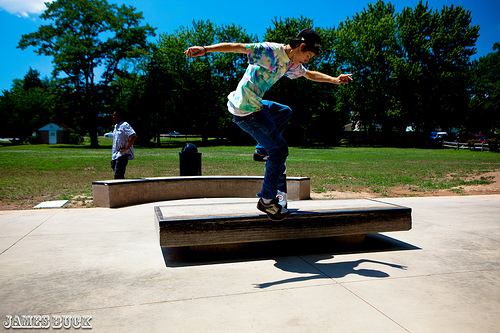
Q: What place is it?
A: It is a park.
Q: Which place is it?
A: It is a park.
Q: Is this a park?
A: Yes, it is a park.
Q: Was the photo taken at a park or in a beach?
A: It was taken at a park.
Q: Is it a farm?
A: No, it is a park.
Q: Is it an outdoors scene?
A: Yes, it is outdoors.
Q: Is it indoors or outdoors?
A: It is outdoors.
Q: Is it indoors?
A: No, it is outdoors.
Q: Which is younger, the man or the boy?
A: The boy is younger than the man.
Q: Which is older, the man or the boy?
A: The man is older than the boy.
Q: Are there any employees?
A: No, there are no employees.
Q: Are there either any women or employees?
A: No, there are no employees or women.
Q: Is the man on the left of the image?
A: Yes, the man is on the left of the image.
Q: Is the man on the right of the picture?
A: No, the man is on the left of the image.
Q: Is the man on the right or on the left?
A: The man is on the left of the image.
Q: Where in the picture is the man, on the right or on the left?
A: The man is on the left of the image.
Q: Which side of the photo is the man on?
A: The man is on the left of the image.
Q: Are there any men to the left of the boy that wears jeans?
A: Yes, there is a man to the left of the boy.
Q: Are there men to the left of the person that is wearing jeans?
A: Yes, there is a man to the left of the boy.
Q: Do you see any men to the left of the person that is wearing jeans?
A: Yes, there is a man to the left of the boy.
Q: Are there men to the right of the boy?
A: No, the man is to the left of the boy.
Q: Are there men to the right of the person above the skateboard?
A: No, the man is to the left of the boy.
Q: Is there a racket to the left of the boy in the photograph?
A: No, there is a man to the left of the boy.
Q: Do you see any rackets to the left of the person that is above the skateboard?
A: No, there is a man to the left of the boy.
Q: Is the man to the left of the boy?
A: Yes, the man is to the left of the boy.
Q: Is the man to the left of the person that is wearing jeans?
A: Yes, the man is to the left of the boy.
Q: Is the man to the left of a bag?
A: No, the man is to the left of the boy.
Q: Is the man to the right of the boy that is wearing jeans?
A: No, the man is to the left of the boy.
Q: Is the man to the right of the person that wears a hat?
A: No, the man is to the left of the boy.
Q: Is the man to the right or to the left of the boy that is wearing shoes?
A: The man is to the left of the boy.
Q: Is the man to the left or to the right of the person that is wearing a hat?
A: The man is to the left of the boy.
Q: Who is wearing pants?
A: The man is wearing pants.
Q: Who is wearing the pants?
A: The man is wearing pants.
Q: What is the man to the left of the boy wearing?
A: The man is wearing trousers.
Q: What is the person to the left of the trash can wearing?
A: The man is wearing trousers.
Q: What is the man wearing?
A: The man is wearing trousers.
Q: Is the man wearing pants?
A: Yes, the man is wearing pants.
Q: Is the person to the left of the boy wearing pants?
A: Yes, the man is wearing pants.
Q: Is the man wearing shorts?
A: No, the man is wearing pants.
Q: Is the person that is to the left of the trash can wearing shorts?
A: No, the man is wearing pants.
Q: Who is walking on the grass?
A: The man is walking on the grass.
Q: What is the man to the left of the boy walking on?
A: The man is walking on the grass.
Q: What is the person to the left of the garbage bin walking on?
A: The man is walking on the grass.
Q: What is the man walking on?
A: The man is walking on the grass.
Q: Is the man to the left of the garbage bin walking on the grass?
A: Yes, the man is walking on the grass.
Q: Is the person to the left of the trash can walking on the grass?
A: Yes, the man is walking on the grass.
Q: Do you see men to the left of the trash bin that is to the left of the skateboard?
A: Yes, there is a man to the left of the trash bin.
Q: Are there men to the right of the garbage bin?
A: No, the man is to the left of the garbage bin.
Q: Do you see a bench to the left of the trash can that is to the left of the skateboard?
A: No, there is a man to the left of the garbage can.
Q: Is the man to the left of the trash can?
A: Yes, the man is to the left of the trash can.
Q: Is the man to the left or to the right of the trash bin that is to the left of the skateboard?
A: The man is to the left of the trash bin.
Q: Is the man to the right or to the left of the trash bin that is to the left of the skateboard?
A: The man is to the left of the trash bin.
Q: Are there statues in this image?
A: No, there are no statues.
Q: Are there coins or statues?
A: No, there are no statues or coins.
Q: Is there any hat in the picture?
A: Yes, there is a hat.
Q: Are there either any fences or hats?
A: Yes, there is a hat.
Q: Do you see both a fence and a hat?
A: No, there is a hat but no fences.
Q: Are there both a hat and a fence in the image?
A: No, there is a hat but no fences.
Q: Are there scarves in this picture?
A: No, there are no scarves.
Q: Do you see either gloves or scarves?
A: No, there are no scarves or gloves.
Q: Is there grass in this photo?
A: Yes, there is grass.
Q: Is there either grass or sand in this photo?
A: Yes, there is grass.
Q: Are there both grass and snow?
A: No, there is grass but no snow.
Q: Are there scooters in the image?
A: No, there are no scooters.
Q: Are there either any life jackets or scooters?
A: No, there are no scooters or life jackets.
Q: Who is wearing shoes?
A: The boy is wearing shoes.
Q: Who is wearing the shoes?
A: The boy is wearing shoes.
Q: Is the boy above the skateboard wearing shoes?
A: Yes, the boy is wearing shoes.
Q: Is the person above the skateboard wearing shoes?
A: Yes, the boy is wearing shoes.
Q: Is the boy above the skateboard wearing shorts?
A: No, the boy is wearing shoes.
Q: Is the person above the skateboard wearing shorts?
A: No, the boy is wearing shoes.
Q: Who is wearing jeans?
A: The boy is wearing jeans.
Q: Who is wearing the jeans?
A: The boy is wearing jeans.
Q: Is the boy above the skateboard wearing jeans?
A: Yes, the boy is wearing jeans.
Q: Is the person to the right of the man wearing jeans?
A: Yes, the boy is wearing jeans.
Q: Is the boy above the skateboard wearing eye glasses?
A: No, the boy is wearing jeans.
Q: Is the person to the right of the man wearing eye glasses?
A: No, the boy is wearing jeans.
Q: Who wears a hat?
A: The boy wears a hat.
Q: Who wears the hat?
A: The boy wears a hat.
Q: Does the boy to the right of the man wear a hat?
A: Yes, the boy wears a hat.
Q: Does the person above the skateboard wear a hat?
A: Yes, the boy wears a hat.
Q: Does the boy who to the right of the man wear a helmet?
A: No, the boy wears a hat.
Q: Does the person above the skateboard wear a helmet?
A: No, the boy wears a hat.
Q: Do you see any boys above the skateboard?
A: Yes, there is a boy above the skateboard.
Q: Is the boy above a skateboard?
A: Yes, the boy is above a skateboard.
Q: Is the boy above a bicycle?
A: No, the boy is above a skateboard.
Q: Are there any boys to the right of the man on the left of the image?
A: Yes, there is a boy to the right of the man.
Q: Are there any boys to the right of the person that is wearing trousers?
A: Yes, there is a boy to the right of the man.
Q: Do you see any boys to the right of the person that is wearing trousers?
A: Yes, there is a boy to the right of the man.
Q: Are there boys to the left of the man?
A: No, the boy is to the right of the man.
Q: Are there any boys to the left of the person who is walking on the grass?
A: No, the boy is to the right of the man.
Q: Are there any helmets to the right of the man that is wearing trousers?
A: No, there is a boy to the right of the man.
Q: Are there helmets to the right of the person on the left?
A: No, there is a boy to the right of the man.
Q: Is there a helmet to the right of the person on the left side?
A: No, there is a boy to the right of the man.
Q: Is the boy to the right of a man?
A: Yes, the boy is to the right of a man.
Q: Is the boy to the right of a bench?
A: No, the boy is to the right of a man.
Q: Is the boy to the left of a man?
A: No, the boy is to the right of a man.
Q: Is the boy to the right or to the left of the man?
A: The boy is to the right of the man.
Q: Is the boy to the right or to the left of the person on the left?
A: The boy is to the right of the man.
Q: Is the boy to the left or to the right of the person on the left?
A: The boy is to the right of the man.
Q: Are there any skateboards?
A: Yes, there is a skateboard.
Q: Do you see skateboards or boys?
A: Yes, there is a skateboard.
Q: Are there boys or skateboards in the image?
A: Yes, there is a skateboard.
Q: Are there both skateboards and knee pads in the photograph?
A: No, there is a skateboard but no knee pads.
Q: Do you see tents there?
A: No, there are no tents.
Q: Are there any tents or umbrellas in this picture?
A: No, there are no tents or umbrellas.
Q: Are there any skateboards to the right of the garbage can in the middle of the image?
A: Yes, there is a skateboard to the right of the trash can.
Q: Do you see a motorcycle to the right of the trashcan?
A: No, there is a skateboard to the right of the trashcan.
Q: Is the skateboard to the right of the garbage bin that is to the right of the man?
A: Yes, the skateboard is to the right of the garbage can.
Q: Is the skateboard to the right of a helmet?
A: No, the skateboard is to the right of the garbage can.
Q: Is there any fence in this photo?
A: No, there are no fences.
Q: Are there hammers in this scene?
A: No, there are no hammers.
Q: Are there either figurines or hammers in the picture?
A: No, there are no hammers or figurines.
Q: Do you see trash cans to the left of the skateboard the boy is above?
A: Yes, there is a trash can to the left of the skateboard.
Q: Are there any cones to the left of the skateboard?
A: No, there is a trash can to the left of the skateboard.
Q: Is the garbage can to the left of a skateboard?
A: Yes, the garbage can is to the left of a skateboard.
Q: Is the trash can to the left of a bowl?
A: No, the trash can is to the left of a skateboard.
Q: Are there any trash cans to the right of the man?
A: Yes, there is a trash can to the right of the man.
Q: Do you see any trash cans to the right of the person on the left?
A: Yes, there is a trash can to the right of the man.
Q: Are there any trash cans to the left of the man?
A: No, the trash can is to the right of the man.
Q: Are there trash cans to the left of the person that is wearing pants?
A: No, the trash can is to the right of the man.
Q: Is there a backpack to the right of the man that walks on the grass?
A: No, there is a trash can to the right of the man.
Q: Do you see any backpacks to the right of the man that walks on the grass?
A: No, there is a trash can to the right of the man.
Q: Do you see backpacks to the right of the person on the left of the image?
A: No, there is a trash can to the right of the man.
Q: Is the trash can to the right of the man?
A: Yes, the trash can is to the right of the man.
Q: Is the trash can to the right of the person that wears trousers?
A: Yes, the trash can is to the right of the man.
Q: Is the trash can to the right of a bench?
A: No, the trash can is to the right of the man.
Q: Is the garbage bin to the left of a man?
A: No, the garbage bin is to the right of a man.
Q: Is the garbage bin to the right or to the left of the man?
A: The garbage bin is to the right of the man.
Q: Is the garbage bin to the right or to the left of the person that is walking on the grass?
A: The garbage bin is to the right of the man.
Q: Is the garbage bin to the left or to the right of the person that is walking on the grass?
A: The garbage bin is to the right of the man.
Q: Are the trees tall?
A: Yes, the trees are tall.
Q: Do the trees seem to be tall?
A: Yes, the trees are tall.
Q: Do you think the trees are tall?
A: Yes, the trees are tall.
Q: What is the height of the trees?
A: The trees are tall.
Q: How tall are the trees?
A: The trees are tall.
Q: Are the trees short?
A: No, the trees are tall.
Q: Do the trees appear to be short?
A: No, the trees are tall.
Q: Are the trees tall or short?
A: The trees are tall.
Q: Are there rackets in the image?
A: No, there are no rackets.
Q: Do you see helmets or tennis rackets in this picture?
A: No, there are no tennis rackets or helmets.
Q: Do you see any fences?
A: No, there are no fences.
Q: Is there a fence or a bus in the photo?
A: No, there are no fences or buses.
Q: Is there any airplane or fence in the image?
A: No, there are no fences or airplanes.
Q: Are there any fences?
A: No, there are no fences.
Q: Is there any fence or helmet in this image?
A: No, there are no fences or helmets.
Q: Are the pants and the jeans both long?
A: Yes, both the pants and the jeans are long.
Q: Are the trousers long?
A: Yes, the trousers are long.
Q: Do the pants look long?
A: Yes, the pants are long.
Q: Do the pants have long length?
A: Yes, the pants are long.